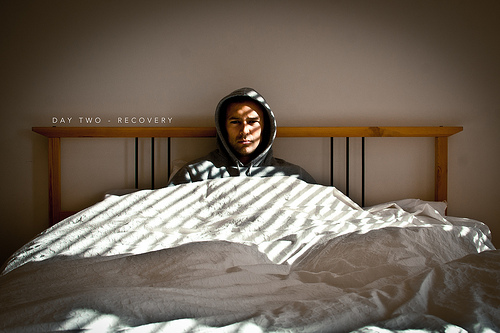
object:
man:
[164, 85, 319, 197]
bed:
[1, 119, 499, 332]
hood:
[210, 86, 280, 163]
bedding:
[2, 168, 499, 332]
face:
[223, 100, 265, 156]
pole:
[132, 136, 144, 190]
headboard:
[29, 119, 466, 228]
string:
[245, 160, 259, 178]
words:
[49, 114, 175, 125]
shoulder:
[163, 149, 227, 189]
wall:
[0, 1, 499, 251]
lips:
[233, 138, 255, 146]